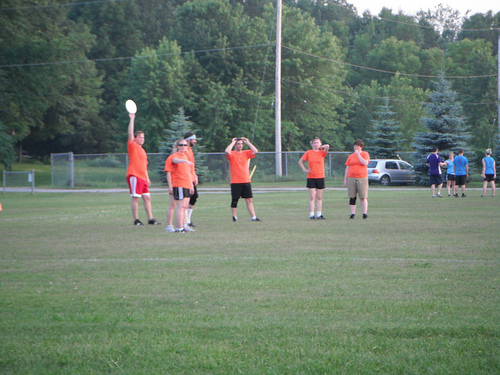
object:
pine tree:
[361, 96, 412, 163]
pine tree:
[154, 105, 208, 186]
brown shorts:
[347, 178, 368, 200]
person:
[343, 139, 371, 220]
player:
[169, 138, 195, 233]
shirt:
[126, 136, 149, 181]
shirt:
[170, 152, 192, 189]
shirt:
[225, 150, 255, 184]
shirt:
[345, 150, 370, 178]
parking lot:
[310, 129, 462, 199]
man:
[425, 147, 446, 198]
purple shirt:
[426, 153, 442, 176]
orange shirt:
[301, 148, 327, 179]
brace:
[231, 198, 239, 208]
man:
[224, 136, 260, 221]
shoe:
[349, 213, 355, 219]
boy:
[481, 148, 497, 197]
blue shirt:
[483, 156, 495, 175]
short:
[126, 174, 150, 197]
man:
[127, 113, 161, 225]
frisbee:
[125, 99, 138, 114]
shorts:
[230, 183, 253, 199]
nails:
[274, 0, 282, 176]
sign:
[28, 173, 33, 182]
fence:
[0, 150, 419, 195]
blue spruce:
[409, 64, 479, 188]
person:
[442, 152, 455, 197]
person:
[452, 148, 469, 197]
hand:
[129, 113, 136, 120]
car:
[367, 158, 417, 186]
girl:
[297, 137, 329, 220]